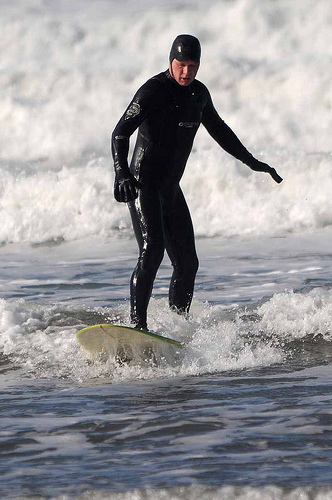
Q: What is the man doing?
A: Surfing.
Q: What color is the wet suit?
A: Black.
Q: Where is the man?
A: In water.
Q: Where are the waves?
A: In background.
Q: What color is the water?
A: White.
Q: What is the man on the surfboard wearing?
A: Wetsuit.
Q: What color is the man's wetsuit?
A: Black.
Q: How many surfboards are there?
A: 1.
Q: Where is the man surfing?
A: Ocean.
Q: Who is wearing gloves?
A: Man surfing.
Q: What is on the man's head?
A: Cap.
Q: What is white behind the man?
A: Sea foam.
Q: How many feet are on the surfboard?
A: 2.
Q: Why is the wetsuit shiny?
A: Water reflection.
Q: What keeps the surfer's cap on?
A: Strap.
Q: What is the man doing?
A: Balancing on a surfboard.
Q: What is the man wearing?
A: A full body wetsuit.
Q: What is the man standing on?
A: Surfboard.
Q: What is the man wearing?
A: A wetsuit.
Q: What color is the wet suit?
A: Black.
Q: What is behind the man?
A: Waves.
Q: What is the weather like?
A: Sunny.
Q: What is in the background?
A: Ocean.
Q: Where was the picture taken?
A: Beach.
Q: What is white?
A: Waves.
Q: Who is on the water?
A: Man.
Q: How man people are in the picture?
A: One.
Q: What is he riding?
A: Surfboard.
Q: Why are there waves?
A: It is windy.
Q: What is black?
A: Suit.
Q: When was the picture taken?
A: Daytime.